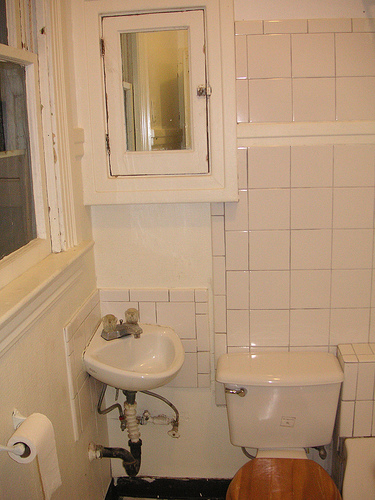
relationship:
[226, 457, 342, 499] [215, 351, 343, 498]
toilet lid on toilet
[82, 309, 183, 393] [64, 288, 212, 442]
corner sink attached to walls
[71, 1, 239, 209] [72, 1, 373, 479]
medicine cabinet attached to wall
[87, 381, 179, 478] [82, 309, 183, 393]
plumbing under corner sink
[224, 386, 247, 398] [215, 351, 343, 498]
flush handle on toilet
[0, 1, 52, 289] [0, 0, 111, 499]
window on wall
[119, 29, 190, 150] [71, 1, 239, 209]
mirror on medicine cabinet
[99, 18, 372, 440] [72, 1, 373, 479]
tile on wall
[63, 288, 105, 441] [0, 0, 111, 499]
tile on wall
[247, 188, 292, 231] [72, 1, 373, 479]
tile on wall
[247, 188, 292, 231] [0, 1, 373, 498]
tile in bathroom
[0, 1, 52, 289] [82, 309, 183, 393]
window next to corner sink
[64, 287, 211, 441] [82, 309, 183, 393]
tiles around corner sink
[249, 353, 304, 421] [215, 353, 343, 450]
reflection on tank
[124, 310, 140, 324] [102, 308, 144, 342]
knob on faucet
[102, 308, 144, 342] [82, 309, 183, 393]
faucet on corner sink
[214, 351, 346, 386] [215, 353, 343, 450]
lid on tank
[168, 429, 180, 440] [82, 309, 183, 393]
valve under corner sink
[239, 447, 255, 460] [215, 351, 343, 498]
pipe behind toilet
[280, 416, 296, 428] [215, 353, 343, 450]
sticker on tank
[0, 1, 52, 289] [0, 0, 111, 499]
window on side of wall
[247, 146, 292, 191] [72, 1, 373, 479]
tile on wall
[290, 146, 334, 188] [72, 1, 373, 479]
tile on wall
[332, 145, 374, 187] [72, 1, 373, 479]
tile on wall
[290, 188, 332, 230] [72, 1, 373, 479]
tile on wall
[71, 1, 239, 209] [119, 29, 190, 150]
medicine cabinet has a built in mirror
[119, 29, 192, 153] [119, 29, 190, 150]
reflection in mirror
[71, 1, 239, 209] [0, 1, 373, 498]
medicine cabinet in bathroom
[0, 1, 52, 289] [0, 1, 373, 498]
window in bathroom